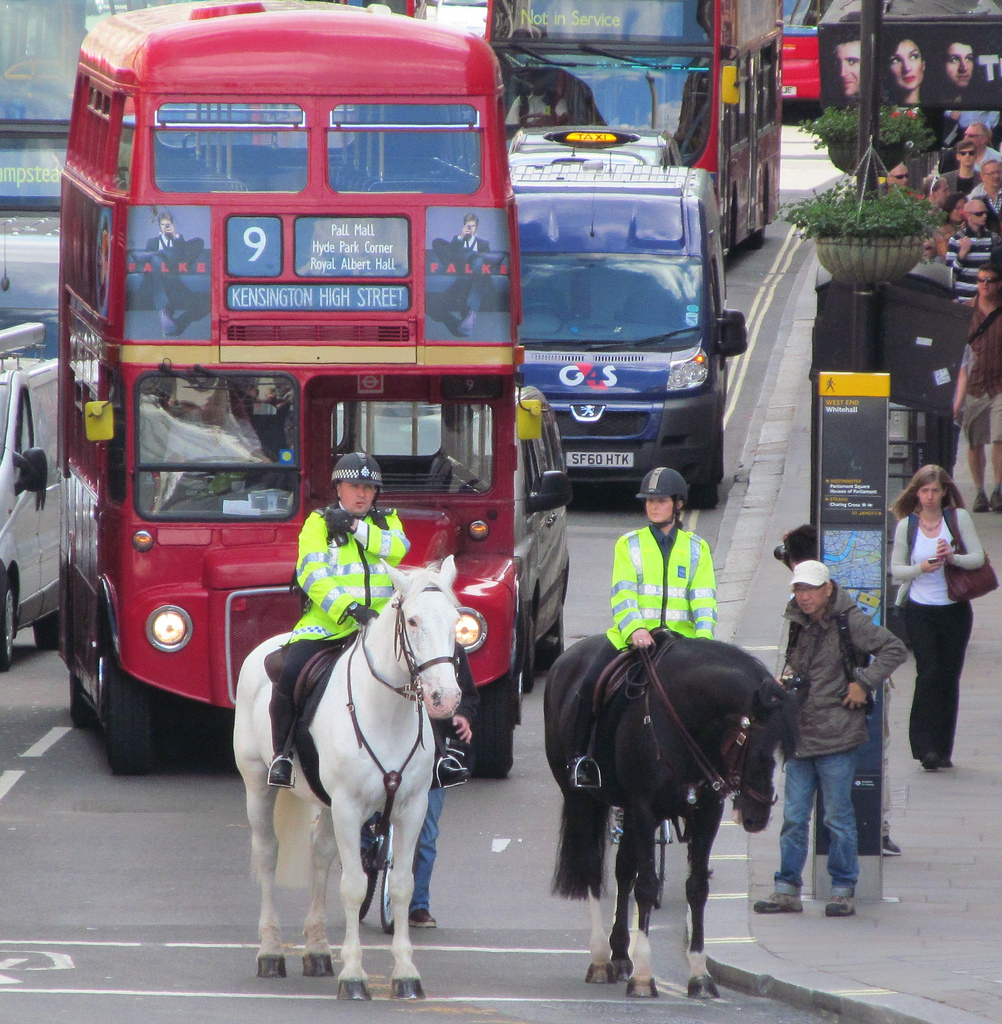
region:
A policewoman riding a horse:
[537, 457, 796, 1020]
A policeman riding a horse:
[218, 447, 458, 1008]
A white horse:
[208, 561, 469, 990]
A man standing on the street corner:
[751, 551, 909, 927]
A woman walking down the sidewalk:
[892, 454, 992, 768]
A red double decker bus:
[56, 1, 578, 789]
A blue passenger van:
[492, 153, 745, 497]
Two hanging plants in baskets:
[796, 0, 952, 303]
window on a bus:
[138, 85, 318, 203]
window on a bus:
[317, 97, 480, 194]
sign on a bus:
[221, 204, 421, 324]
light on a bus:
[115, 569, 199, 666]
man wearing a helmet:
[302, 450, 403, 583]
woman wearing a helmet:
[616, 448, 729, 654]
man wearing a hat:
[785, 542, 915, 680]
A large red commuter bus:
[50, 4, 530, 784]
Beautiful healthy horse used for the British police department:
[527, 620, 814, 1005]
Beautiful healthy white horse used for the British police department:
[230, 549, 470, 1001]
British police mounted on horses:
[227, 439, 819, 1005]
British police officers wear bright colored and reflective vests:
[266, 441, 725, 654]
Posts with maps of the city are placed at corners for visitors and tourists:
[810, 368, 890, 870]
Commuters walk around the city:
[737, 115, 997, 920]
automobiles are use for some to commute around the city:
[1, 0, 824, 788]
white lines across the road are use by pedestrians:
[3, 899, 734, 1017]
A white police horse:
[233, 549, 466, 1001]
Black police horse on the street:
[546, 630, 810, 1002]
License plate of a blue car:
[566, 449, 636, 469]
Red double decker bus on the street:
[59, 0, 522, 781]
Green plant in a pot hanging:
[781, 184, 948, 236]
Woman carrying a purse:
[887, 462, 997, 772]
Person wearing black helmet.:
[335, 452, 400, 496]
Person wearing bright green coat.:
[291, 494, 401, 650]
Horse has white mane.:
[402, 555, 462, 605]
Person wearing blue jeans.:
[782, 764, 863, 897]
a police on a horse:
[212, 428, 486, 1015]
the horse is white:
[221, 546, 480, 1021]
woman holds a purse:
[878, 448, 1000, 787]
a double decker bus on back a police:
[26, 8, 581, 1009]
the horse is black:
[530, 615, 797, 1013]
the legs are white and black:
[568, 831, 732, 1021]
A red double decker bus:
[40, 1, 551, 818]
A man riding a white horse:
[207, 417, 487, 1012]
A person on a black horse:
[525, 438, 817, 1013]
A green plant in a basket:
[771, 166, 954, 289]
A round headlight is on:
[127, 578, 204, 672]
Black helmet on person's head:
[608, 446, 708, 543]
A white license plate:
[552, 429, 643, 486]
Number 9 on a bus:
[210, 194, 298, 288]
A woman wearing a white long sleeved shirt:
[871, 448, 995, 609]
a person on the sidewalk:
[870, 477, 991, 648]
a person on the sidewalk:
[937, 296, 998, 364]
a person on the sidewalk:
[953, 198, 998, 262]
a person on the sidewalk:
[790, 164, 998, 196]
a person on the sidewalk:
[934, 145, 989, 230]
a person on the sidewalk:
[961, 116, 998, 153]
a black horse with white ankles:
[540, 630, 804, 1003]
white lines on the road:
[0, 929, 734, 1013]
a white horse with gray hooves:
[229, 554, 468, 1007]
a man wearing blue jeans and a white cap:
[766, 560, 903, 922]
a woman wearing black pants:
[882, 460, 999, 773]